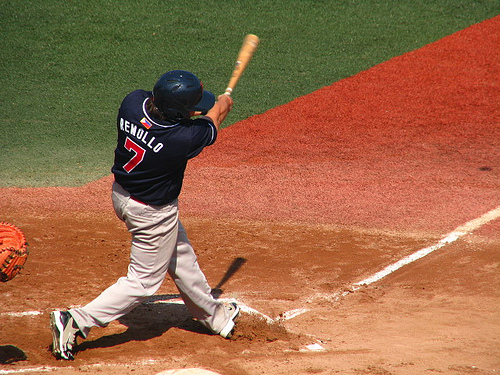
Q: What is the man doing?
A: Swinging bat.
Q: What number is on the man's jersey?
A: 7.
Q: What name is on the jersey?
A: Renollo.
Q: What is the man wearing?
A: Baseball uniform.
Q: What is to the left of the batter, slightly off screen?
A: Catcher's mitt.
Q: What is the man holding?
A: Ball bat.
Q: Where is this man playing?
A: Ball field.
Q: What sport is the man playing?
A: Baseball.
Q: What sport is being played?
A: Baseball.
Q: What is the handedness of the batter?
A: Right handed.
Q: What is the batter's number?
A: 7.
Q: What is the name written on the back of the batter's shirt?
A: Rewollo.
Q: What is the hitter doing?
A: Swinging.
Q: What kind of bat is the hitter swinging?
A: Wooden bat.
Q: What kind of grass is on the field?
A: Artificial grass.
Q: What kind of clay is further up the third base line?
A: Artificial clay.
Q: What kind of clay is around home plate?
A: Natural clay.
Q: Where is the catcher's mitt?
A: To the left of the batter.